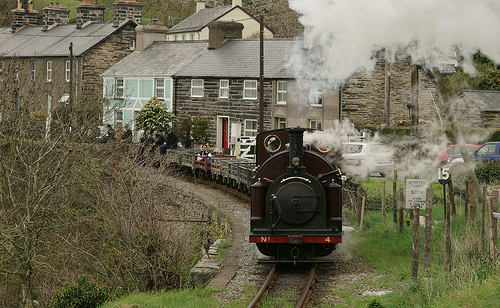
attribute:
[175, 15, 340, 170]
house — two-story, big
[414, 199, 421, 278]
post — small, wooden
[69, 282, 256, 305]
grass — light green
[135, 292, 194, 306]
grass — wild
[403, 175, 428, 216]
sign — black, white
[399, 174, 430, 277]
sign — white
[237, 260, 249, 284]
rocks — small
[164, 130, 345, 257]
train — large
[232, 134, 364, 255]
train — small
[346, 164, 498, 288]
fence — wooden 